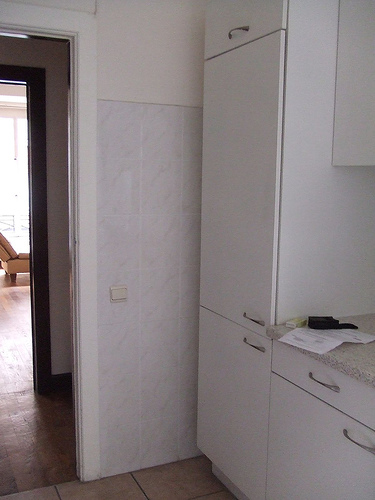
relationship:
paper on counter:
[276, 326, 374, 358] [267, 312, 374, 390]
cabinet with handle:
[197, 30, 287, 337] [243, 308, 269, 332]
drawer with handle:
[270, 338, 374, 431] [308, 369, 339, 397]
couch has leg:
[0, 235, 33, 284] [10, 270, 18, 283]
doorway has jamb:
[1, 0, 105, 488] [68, 32, 101, 482]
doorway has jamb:
[1, 60, 56, 393] [23, 82, 53, 398]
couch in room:
[0, 235, 33, 284] [1, 85, 31, 390]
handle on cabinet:
[226, 24, 255, 38] [203, 0, 285, 61]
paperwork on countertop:
[276, 326, 374, 358] [267, 312, 374, 390]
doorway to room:
[1, 60, 56, 393] [1, 85, 31, 390]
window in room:
[1, 104, 27, 243] [1, 85, 31, 390]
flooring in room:
[2, 272, 33, 395] [1, 85, 31, 390]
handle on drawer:
[308, 369, 339, 397] [270, 338, 374, 431]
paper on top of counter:
[276, 326, 374, 358] [267, 312, 374, 390]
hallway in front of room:
[0, 390, 76, 494] [1, 85, 31, 390]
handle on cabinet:
[341, 428, 374, 455] [263, 375, 373, 498]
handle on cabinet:
[243, 331, 268, 356] [195, 306, 275, 494]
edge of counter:
[269, 327, 374, 383] [267, 312, 374, 390]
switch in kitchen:
[110, 281, 133, 305] [101, 1, 374, 496]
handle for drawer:
[308, 369, 339, 397] [270, 338, 374, 431]